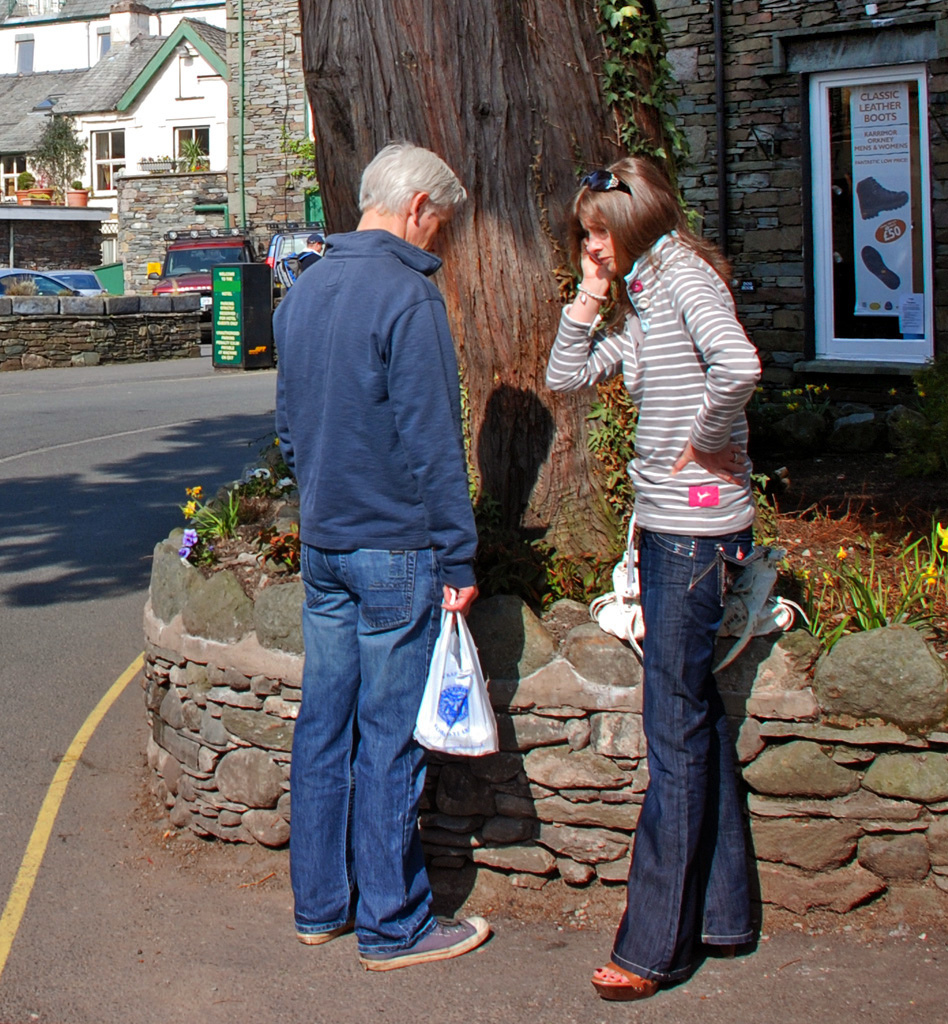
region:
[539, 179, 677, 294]
the head of a woman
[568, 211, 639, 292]
the face of a woman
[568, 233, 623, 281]
the mouth of a woman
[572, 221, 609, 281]
the nose of a woman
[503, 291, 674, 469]
the arm of a woman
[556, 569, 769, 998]
the legs of a woman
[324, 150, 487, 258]
the head of a man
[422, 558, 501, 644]
the hand of a man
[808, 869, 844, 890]
brick on the wall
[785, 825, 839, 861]
brick on the wall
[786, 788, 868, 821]
brick on the wall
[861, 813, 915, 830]
brick on the wall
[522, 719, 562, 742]
brick on the wall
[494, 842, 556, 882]
brick on the wall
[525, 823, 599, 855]
brick on the wall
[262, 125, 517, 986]
man in blue sweater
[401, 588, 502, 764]
white and blue bag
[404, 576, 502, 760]
a blue and white plastic bag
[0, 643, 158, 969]
a long painted yellow line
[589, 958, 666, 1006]
the top of a woman's sandal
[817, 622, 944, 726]
a large gray rock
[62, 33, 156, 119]
the roof of a building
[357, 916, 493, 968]
a man's old worn shoe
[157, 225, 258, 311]
the front of a red suv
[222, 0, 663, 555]
a large tree branch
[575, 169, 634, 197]
dark black sunglasses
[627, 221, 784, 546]
woman has her hand on her hip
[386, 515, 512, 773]
man is holding a shopping bag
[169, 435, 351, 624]
flowers in front of the tree